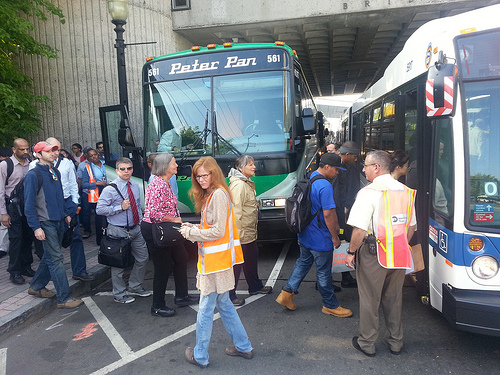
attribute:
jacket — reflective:
[171, 191, 259, 261]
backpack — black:
[282, 174, 329, 235]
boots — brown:
[275, 284, 352, 314]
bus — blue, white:
[137, 38, 326, 248]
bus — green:
[109, 40, 336, 315]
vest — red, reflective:
[368, 185, 428, 273]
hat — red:
[33, 141, 60, 154]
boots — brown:
[273, 268, 448, 365]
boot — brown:
[272, 288, 305, 304]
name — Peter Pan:
[168, 54, 260, 71]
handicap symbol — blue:
[433, 230, 452, 251]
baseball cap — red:
[30, 139, 60, 154]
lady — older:
[147, 150, 199, 318]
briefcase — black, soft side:
[87, 209, 137, 277]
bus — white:
[328, 37, 499, 265]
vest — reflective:
[171, 174, 279, 292]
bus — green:
[122, 43, 347, 244]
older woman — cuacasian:
[144, 151, 195, 320]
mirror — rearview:
[282, 109, 343, 159]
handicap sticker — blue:
[435, 229, 447, 254]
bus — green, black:
[97, 42, 329, 237]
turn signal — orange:
[465, 230, 483, 253]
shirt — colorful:
[142, 174, 178, 222]